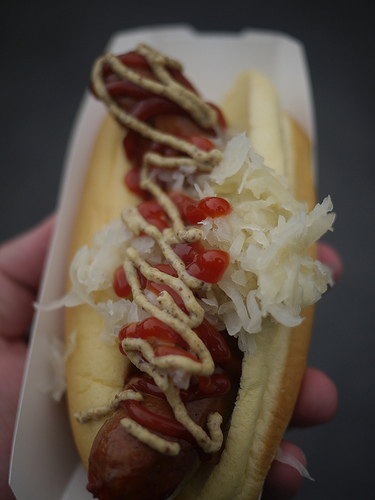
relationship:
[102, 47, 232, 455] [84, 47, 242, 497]
ketchup on hot dog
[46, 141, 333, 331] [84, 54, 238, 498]
sauerkraut on hotdog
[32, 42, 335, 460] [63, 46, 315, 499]
toppings on hotdog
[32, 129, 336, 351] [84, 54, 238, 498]
sauerkraut on hotdog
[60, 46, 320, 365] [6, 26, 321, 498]
hot dog in box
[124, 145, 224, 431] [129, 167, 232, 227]
line of ketchup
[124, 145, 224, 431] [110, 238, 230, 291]
line of ketchup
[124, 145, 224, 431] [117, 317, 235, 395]
line of ketchup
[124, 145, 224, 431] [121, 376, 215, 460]
line of ketchup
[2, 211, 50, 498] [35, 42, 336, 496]
palm holding hotdog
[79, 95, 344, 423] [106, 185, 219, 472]
box for hotdog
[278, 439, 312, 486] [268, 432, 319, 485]
sauerkraut on finger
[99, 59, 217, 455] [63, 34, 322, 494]
mustard on hot dog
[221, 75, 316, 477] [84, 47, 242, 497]
bun under hot dog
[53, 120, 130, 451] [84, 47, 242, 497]
bun under hot dog